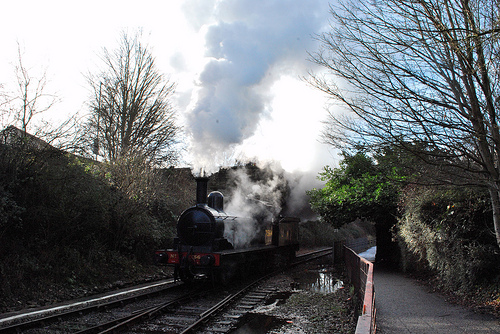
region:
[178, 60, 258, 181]
The trian is making smoke.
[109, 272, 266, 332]
A pair of train tracks.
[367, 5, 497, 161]
The trees have no leaves.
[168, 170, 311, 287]
The train engine is black.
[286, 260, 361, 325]
Water is in a puddle.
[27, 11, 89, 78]
The sky is bright.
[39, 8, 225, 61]
The sky is cloudy.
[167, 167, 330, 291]
The trian is moving.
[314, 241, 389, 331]
A fence is beside the train.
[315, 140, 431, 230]
One tree has leaves.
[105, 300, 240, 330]
metal train tracks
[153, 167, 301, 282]
black train on train tracks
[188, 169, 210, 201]
black chimney on train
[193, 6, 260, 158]
white grey smoke on black train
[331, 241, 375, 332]
side fence on side of train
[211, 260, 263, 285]
wheels on train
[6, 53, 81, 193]
brown branches on tree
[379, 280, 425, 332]
grey cement sidewalk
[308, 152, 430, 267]
green tree leaves on a tree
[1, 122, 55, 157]
roof on building top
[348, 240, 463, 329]
rail road walk way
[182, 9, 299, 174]
steam from running train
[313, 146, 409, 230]
tree hanging over walk way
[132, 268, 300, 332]
rail road tracksbeing used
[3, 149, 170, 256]
side hill on rail road tracks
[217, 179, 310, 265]
smoke coming off train engine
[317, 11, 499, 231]
bare tree branches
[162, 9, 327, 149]
steam gathering in sky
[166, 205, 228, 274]
front part of train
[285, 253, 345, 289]
water puddle on tracks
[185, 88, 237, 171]
Smoke from a steam engine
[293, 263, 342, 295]
Puddle of water near a train track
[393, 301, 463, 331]
Grey bricks on a sidewalk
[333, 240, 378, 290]
Red fence behind train tracks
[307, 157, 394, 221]
Green leaves on a tree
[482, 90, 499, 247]
Bare tree trunk by a sidewalk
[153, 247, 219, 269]
Bumper on a train engine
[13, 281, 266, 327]
Two sets of train tracks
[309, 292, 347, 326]
Gravel on a train track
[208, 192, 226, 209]
Boiler plate on a train engine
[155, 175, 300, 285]
a small black train engine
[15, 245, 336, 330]
a small set of train tracks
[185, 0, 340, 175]
steam coming from the train engine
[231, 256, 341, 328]
puddles next to the tracks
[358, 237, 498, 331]
a sidewalk next to the train tracks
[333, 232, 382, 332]
a fence next to the sidewalk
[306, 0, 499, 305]
foliage next to the sidewalk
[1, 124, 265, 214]
buildings behind the train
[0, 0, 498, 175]
a steam-obscured sky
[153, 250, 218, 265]
red bumper of the train engine